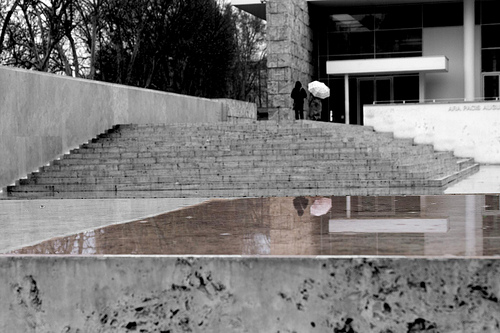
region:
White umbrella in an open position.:
[307, 80, 329, 100]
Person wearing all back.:
[289, 79, 306, 121]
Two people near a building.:
[292, 81, 324, 120]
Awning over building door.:
[325, 55, 450, 72]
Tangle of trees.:
[75, 4, 248, 86]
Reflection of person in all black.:
[292, 196, 307, 216]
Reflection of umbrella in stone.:
[310, 196, 334, 216]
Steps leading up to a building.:
[8, 121, 478, 197]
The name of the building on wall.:
[446, 102, 498, 112]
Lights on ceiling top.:
[332, 11, 368, 36]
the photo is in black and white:
[2, 0, 498, 327]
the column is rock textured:
[262, 3, 319, 122]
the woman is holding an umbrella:
[309, 78, 329, 121]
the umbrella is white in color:
[308, 79, 329, 99]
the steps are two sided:
[5, 120, 479, 195]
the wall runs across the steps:
[2, 65, 254, 195]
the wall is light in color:
[362, 97, 490, 161]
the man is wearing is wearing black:
[290, 80, 307, 113]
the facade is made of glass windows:
[318, 10, 498, 125]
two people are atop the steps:
[291, 78, 327, 121]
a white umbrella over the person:
[305, 76, 334, 102]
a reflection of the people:
[288, 194, 333, 219]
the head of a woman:
[292, 77, 305, 89]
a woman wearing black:
[288, 77, 310, 120]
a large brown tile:
[1, 192, 498, 256]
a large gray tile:
[0, 197, 239, 254]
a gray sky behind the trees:
[1, 0, 274, 82]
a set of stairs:
[0, 120, 481, 198]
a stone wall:
[266, 0, 311, 120]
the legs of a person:
[291, 103, 308, 121]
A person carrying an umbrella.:
[305, 81, 332, 121]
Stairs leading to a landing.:
[326, 100, 481, 187]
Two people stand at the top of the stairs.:
[291, 78, 328, 119]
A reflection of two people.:
[288, 193, 333, 215]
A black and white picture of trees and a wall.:
[7, 0, 265, 123]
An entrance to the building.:
[352, 74, 397, 122]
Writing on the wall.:
[447, 101, 499, 113]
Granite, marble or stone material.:
[3, 254, 161, 326]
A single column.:
[457, 1, 481, 100]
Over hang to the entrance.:
[324, 53, 447, 106]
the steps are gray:
[140, 125, 306, 198]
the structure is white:
[316, 45, 459, 83]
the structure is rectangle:
[318, 48, 455, 89]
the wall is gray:
[14, 85, 74, 151]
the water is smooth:
[65, 180, 489, 277]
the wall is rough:
[142, 264, 307, 331]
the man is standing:
[277, 77, 315, 128]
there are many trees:
[2, 0, 196, 85]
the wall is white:
[417, 27, 485, 97]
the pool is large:
[20, 201, 497, 265]